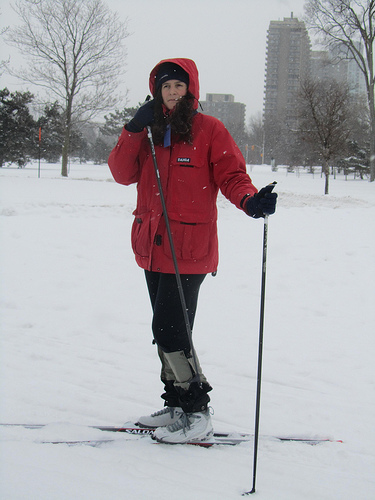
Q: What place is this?
A: It is a field.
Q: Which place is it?
A: It is a field.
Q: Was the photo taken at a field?
A: Yes, it was taken in a field.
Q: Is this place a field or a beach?
A: It is a field.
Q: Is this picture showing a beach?
A: No, the picture is showing a field.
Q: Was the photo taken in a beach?
A: No, the picture was taken in a field.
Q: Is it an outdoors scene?
A: Yes, it is outdoors.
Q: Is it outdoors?
A: Yes, it is outdoors.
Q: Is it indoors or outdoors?
A: It is outdoors.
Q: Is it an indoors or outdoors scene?
A: It is outdoors.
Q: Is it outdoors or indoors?
A: It is outdoors.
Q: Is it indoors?
A: No, it is outdoors.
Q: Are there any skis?
A: Yes, there are skis.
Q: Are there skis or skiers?
A: Yes, there are skis.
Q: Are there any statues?
A: No, there are no statues.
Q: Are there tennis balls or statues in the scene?
A: No, there are no statues or tennis balls.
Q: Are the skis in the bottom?
A: Yes, the skis are in the bottom of the image.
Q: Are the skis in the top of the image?
A: No, the skis are in the bottom of the image.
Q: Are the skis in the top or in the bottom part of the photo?
A: The skis are in the bottom of the image.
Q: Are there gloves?
A: Yes, there are gloves.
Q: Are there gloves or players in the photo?
A: Yes, there are gloves.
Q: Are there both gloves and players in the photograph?
A: No, there are gloves but no players.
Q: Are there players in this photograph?
A: No, there are no players.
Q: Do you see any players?
A: No, there are no players.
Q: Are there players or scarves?
A: No, there are no players or scarves.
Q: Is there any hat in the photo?
A: Yes, there is a hat.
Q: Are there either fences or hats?
A: Yes, there is a hat.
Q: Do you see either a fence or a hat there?
A: Yes, there is a hat.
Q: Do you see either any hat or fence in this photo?
A: Yes, there is a hat.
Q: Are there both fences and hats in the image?
A: No, there is a hat but no fences.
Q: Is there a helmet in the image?
A: No, there are no helmets.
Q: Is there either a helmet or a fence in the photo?
A: No, there are no helmets or fences.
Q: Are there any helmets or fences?
A: No, there are no helmets or fences.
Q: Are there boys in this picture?
A: No, there are no boys.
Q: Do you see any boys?
A: No, there are no boys.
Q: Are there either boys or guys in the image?
A: No, there are no boys or guys.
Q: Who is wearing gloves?
A: The lady is wearing gloves.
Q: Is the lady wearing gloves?
A: Yes, the lady is wearing gloves.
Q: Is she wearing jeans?
A: No, the lady is wearing gloves.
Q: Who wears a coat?
A: The lady wears a coat.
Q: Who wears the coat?
A: The lady wears a coat.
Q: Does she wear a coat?
A: Yes, the lady wears a coat.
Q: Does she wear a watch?
A: No, the lady wears a coat.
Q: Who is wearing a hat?
A: The lady is wearing a hat.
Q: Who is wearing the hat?
A: The lady is wearing a hat.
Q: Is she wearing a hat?
A: Yes, the lady is wearing a hat.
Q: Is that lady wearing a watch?
A: No, the lady is wearing a hat.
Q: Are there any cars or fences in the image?
A: No, there are no cars or fences.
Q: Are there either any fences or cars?
A: No, there are no cars or fences.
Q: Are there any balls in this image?
A: No, there are no balls.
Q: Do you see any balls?
A: No, there are no balls.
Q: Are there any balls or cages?
A: No, there are no balls or cages.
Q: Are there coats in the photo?
A: Yes, there is a coat.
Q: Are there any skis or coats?
A: Yes, there is a coat.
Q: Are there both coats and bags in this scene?
A: No, there is a coat but no bags.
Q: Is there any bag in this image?
A: No, there are no bags.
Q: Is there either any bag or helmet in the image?
A: No, there are no bags or helmets.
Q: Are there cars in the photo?
A: No, there are no cars.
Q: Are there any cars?
A: No, there are no cars.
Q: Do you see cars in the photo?
A: No, there are no cars.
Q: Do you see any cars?
A: No, there are no cars.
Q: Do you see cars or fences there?
A: No, there are no cars or fences.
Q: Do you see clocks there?
A: No, there are no clocks.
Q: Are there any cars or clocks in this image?
A: No, there are no clocks or cars.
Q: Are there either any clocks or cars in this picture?
A: No, there are no clocks or cars.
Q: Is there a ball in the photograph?
A: No, there are no balls.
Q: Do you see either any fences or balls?
A: No, there are no balls or fences.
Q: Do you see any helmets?
A: No, there are no helmets.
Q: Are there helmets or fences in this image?
A: No, there are no helmets or fences.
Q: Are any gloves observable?
A: Yes, there are gloves.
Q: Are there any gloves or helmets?
A: Yes, there are gloves.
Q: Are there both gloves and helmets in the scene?
A: No, there are gloves but no helmets.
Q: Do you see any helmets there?
A: No, there are no helmets.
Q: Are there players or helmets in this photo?
A: No, there are no helmets or players.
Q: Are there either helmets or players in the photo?
A: No, there are no helmets or players.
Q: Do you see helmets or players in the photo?
A: No, there are no helmets or players.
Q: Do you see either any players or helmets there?
A: No, there are no helmets or players.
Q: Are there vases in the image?
A: No, there are no vases.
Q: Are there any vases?
A: No, there are no vases.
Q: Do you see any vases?
A: No, there are no vases.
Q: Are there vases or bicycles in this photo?
A: No, there are no vases or bicycles.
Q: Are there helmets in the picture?
A: No, there are no helmets.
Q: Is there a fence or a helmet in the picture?
A: No, there are no helmets or fences.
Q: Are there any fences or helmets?
A: No, there are no helmets or fences.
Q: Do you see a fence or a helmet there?
A: No, there are no helmets or fences.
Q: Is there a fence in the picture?
A: No, there are no fences.